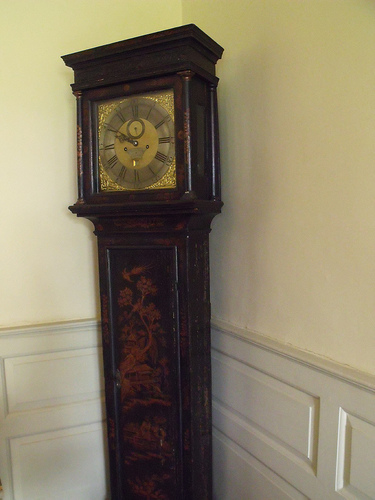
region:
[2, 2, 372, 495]
white walls of room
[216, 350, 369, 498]
panels on bottom half of floor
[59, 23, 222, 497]
clock in corner of room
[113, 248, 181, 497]
door on front of clock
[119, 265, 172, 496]
gold design on wood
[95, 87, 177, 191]
square around face of clock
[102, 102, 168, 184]
roman numerals on clock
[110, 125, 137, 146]
two hands on clock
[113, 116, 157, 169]
gold circle in the middle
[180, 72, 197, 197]
column on corner of clock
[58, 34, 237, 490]
tall grandfather clock in corner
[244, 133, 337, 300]
wall is light yellow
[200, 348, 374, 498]
white wall nearer floor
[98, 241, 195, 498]
floral image on clock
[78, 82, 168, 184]
clock has gold face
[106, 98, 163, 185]
clock has roman numerals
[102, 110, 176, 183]
roman numerals are black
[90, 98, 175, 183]
clock hands are black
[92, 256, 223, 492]
red wood toward base of clock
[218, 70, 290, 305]
clock is casting shadow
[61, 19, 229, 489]
grandfather clock in a corner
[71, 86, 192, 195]
face of the clock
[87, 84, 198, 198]
the clock has roman numerals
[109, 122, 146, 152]
minute and hour hands on the clock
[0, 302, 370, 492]
white paneling on the wall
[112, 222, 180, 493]
decor on the front of the clock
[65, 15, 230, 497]
an antique grandfather clock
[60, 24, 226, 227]
top of the grandfather clock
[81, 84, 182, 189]
golden face clock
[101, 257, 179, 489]
floral decor on the clock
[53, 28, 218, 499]
a big clock sits in the corner of a room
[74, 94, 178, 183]
the center of the clock gold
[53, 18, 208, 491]
the clock is made of wood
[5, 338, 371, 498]
the bottom portion of the wall is white in color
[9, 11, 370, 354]
the top portion of the wall is cream in color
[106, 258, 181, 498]
the front of the clock has s decorative carving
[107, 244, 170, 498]
the decorative portion is lighter than the rest of the wod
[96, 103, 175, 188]
the time is set to 9:50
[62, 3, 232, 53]
no items are placed on top of the clock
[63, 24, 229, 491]
the clock has been stained a dark color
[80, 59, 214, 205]
The clock is encased in wood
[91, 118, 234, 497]
an enclosed grandfather clock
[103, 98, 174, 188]
the clock is golden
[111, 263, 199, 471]
The clock is made of wood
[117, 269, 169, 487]
Floral pattern on the outside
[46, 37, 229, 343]
the clock is in the corner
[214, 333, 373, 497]
the wall is made of wood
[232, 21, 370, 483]
the wall is bare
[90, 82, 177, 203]
The clock is very shiny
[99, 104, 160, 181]
there are two dials